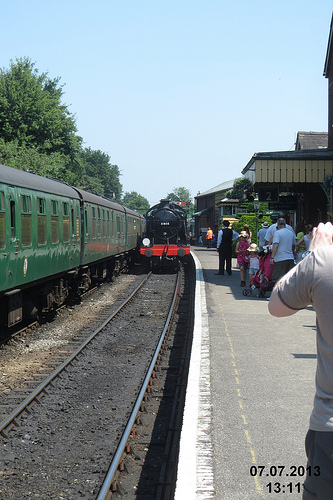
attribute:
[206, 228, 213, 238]
vest — orange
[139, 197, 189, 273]
train — black and red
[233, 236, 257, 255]
outfit — pink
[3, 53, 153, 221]
trees — green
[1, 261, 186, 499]
tracks — set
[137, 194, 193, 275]
train — red, black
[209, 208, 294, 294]
people — grouped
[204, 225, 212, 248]
man — standing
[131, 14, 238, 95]
sky — clear, blue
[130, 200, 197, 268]
train car — green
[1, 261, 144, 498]
gravel — beside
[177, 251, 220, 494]
stripe — long, white, painted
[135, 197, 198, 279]
train — black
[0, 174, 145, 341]
train — green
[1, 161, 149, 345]
train — opposite, green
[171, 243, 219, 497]
line — white